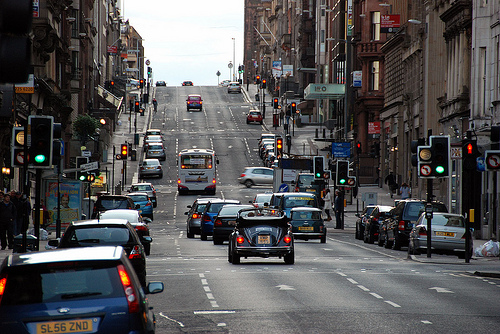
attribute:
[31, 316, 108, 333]
license plate — yellow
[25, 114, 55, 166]
stoplight — green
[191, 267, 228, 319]
lines — white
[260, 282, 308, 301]
arrow — pointing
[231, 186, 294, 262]
car — blue, convertible, red, stopped, crossing, beetle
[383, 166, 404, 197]
person — standing, stepping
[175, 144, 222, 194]
bus — white, traveling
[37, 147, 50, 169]
light — green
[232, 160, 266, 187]
car — white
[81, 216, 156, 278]
car — red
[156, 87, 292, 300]
street — san francisco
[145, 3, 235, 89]
sky — cloudy, white